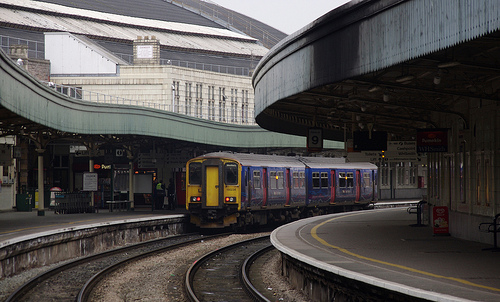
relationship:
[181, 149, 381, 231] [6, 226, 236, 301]
train on track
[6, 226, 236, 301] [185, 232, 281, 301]
track near track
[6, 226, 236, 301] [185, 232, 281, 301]
track next to track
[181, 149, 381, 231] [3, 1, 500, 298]
train in station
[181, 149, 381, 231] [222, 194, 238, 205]
train has lights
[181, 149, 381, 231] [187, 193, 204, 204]
train has lights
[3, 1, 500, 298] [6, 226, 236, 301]
station has track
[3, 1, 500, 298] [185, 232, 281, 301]
station has track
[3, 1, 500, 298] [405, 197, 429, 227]
station has bench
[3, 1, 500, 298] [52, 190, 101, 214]
station has bench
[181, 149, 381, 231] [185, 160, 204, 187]
train has window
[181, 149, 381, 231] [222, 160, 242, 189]
train has window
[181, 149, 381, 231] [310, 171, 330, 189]
train has window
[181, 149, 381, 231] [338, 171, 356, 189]
train has window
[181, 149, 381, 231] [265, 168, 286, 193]
train has window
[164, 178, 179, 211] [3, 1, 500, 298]
person at station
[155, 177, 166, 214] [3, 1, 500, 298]
person at station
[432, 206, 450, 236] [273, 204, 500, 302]
posterboard on walkway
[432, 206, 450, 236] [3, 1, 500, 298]
posterboard in station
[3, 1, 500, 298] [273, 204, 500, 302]
station has walkway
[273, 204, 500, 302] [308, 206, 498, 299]
walkway has line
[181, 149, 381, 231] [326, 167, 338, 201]
train has door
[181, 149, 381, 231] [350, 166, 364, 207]
train has door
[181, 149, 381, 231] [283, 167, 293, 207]
train has door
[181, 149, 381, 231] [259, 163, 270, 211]
train has door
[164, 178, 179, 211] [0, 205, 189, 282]
person on platform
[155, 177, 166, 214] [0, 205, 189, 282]
person on platform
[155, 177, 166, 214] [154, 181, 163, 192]
person wearing vest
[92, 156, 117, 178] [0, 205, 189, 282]
sign on platform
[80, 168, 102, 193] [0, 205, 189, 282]
sign on platform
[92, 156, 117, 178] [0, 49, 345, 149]
sign below roof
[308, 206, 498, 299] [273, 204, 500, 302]
line on walkway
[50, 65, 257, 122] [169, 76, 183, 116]
building has window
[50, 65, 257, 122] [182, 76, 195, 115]
building has window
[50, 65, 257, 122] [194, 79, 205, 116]
building has window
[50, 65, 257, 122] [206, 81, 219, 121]
building has window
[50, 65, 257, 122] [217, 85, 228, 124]
building has window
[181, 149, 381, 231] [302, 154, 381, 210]
train has rear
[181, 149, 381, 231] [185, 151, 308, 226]
train has front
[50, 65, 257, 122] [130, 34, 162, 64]
building has chimney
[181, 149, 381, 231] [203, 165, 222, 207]
train has door